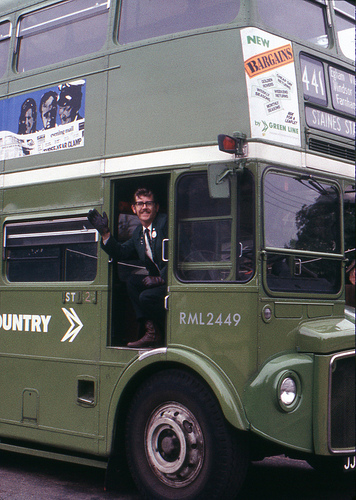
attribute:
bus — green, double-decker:
[1, 4, 354, 475]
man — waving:
[92, 189, 166, 345]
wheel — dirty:
[131, 371, 233, 492]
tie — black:
[147, 227, 151, 257]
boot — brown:
[125, 323, 157, 346]